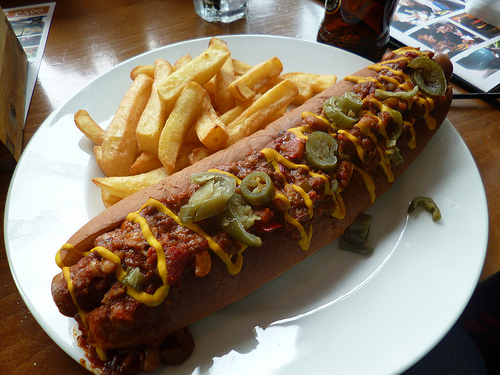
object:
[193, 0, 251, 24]
candle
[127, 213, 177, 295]
mustard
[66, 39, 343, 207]
fries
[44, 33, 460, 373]
hot dog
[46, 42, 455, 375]
weiner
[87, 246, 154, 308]
plastic mustard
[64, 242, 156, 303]
stream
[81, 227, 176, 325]
sauce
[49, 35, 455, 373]
food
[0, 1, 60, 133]
paper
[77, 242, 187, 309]
chili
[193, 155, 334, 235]
chili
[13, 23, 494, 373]
plate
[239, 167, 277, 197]
pepper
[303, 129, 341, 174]
jalapenos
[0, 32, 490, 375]
bun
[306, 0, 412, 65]
bottle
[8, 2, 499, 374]
table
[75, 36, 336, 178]
pile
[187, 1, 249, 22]
glass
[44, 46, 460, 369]
roll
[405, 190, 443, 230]
slice